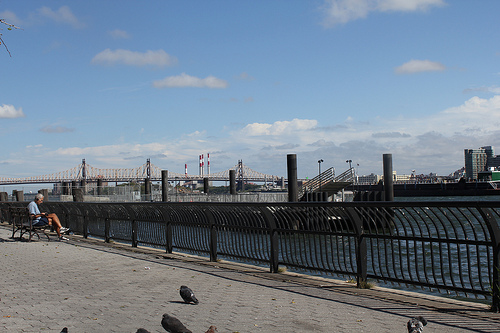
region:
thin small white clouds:
[80, 34, 240, 117]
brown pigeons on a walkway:
[157, 277, 213, 328]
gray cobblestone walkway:
[15, 241, 101, 313]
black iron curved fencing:
[209, 190, 429, 283]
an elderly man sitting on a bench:
[9, 180, 74, 240]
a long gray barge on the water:
[50, 147, 415, 211]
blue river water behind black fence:
[394, 232, 481, 279]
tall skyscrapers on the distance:
[424, 126, 496, 171]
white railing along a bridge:
[3, 162, 245, 179]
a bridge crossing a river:
[7, 146, 282, 204]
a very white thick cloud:
[98, 46, 168, 72]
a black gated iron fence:
[391, 233, 455, 251]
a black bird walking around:
[176, 288, 198, 298]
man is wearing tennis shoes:
[65, 229, 68, 234]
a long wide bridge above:
[18, 171, 82, 176]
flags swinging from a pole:
[193, 151, 211, 173]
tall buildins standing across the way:
[469, 153, 490, 173]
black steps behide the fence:
[291, 167, 349, 192]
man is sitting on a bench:
[12, 223, 32, 240]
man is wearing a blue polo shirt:
[31, 206, 39, 211]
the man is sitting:
[21, 177, 73, 246]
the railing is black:
[128, 194, 279, 254]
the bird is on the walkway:
[156, 270, 216, 312]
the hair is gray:
[28, 190, 52, 197]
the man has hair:
[33, 190, 46, 198]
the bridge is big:
[31, 147, 303, 186]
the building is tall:
[453, 137, 491, 184]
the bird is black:
[154, 271, 206, 311]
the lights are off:
[308, 141, 366, 169]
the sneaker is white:
[51, 224, 74, 242]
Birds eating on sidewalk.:
[21, 264, 443, 331]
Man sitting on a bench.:
[6, 180, 83, 252]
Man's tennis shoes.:
[53, 221, 73, 242]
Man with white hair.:
[10, 184, 72, 246]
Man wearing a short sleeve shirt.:
[13, 180, 70, 237]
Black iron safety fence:
[62, 189, 482, 294]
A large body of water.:
[140, 187, 484, 289]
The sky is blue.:
[46, 55, 165, 123]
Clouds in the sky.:
[115, 58, 482, 168]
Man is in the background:
[21, 183, 75, 246]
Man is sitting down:
[16, 185, 83, 250]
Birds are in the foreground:
[113, 275, 229, 332]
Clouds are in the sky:
[6, 3, 494, 165]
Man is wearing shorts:
[32, 209, 73, 244]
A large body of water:
[111, 165, 498, 299]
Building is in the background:
[457, 136, 499, 181]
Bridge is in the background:
[1, 151, 291, 193]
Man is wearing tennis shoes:
[51, 221, 74, 251]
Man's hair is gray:
[24, 188, 52, 210]